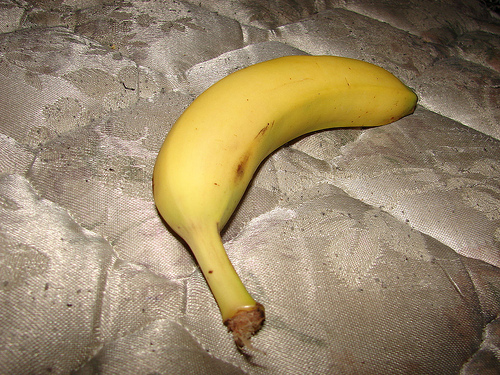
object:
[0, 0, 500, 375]
quilt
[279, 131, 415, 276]
bed cover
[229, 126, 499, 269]
white couch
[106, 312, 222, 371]
stitching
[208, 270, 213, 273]
black dot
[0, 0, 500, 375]
bed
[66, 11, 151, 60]
flowers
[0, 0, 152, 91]
stems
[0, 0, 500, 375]
cover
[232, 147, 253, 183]
brown spots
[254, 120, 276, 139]
brown spots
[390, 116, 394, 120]
brown spots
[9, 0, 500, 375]
couch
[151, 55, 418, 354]
banana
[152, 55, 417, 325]
peel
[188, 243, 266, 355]
stalk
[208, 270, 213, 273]
dot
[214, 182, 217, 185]
dot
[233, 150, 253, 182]
dot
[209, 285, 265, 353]
end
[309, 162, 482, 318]
creases